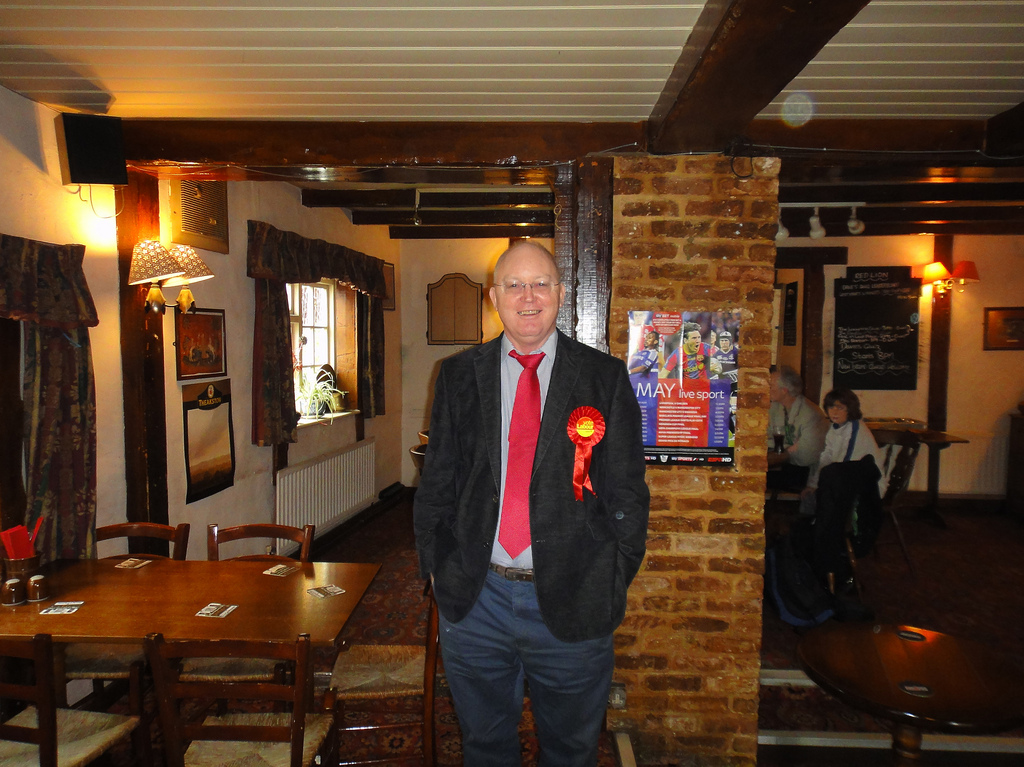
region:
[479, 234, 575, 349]
Head of a man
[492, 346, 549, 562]
Tie of a man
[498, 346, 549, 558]
Red tie of a man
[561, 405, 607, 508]
Ribbon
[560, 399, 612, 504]
Red ribbon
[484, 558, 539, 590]
Belt on a man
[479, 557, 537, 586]
Black belt on a man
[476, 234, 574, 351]
Man is standing and smiling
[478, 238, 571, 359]
Man is facing the camera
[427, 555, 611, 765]
Pants on a man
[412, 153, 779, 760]
man standing next to a brick wall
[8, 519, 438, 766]
a wooden table surrounded by chairs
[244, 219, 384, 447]
drapes covering a window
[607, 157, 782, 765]
a purple and red poster on a brick wall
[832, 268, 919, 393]
a black board with white chalk writing on it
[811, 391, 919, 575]
woman wearing a white shirt sitting on a chair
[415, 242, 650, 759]
man wearing a pink tie and black jacket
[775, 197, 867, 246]
three white light fixtures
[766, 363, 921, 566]
a man with gray hair sitting next to a woman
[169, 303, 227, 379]
a black framed painting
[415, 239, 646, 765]
the man is standing up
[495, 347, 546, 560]
the tie is red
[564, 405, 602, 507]
the ribbon is red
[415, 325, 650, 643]
the jacket is black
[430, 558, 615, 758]
the pants are blue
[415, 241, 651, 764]
the man is wearing glasses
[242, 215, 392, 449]
the curtains are hanging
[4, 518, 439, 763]
the chairs around the table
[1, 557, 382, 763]
the table is made of wood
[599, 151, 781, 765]
the brick wall is small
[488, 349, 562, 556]
a man wearing a red tie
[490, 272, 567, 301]
a man wearing eye glasses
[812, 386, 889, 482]
a woman sitting down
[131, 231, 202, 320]
two light fixtures attached to a wall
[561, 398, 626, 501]
a man wearing a red and yellow ribbon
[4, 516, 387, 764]
a wood table and chairs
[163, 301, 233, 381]
a picture hanging on a wall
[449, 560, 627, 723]
a man wearing blue pants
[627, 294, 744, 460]
a sign hanging on a brick column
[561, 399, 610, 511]
red award ribbon on a lapel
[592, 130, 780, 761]
brick support beam with a sign on it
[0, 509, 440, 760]
table set for five people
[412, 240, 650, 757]
Man with red tie and ribbon smiling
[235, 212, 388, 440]
window surrounded by dark curtains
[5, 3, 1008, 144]
wood slat ceiling panels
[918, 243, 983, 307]
two light fixture with one light out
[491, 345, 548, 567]
long plain red tie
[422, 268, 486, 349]
dart board with doors closed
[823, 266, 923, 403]
caulk board with writing on it